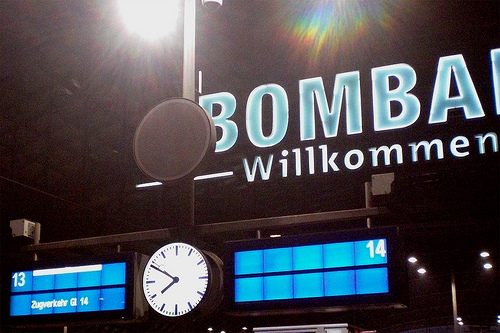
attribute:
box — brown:
[6, 217, 37, 242]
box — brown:
[368, 170, 399, 196]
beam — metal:
[19, 202, 389, 255]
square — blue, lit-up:
[232, 252, 259, 273]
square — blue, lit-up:
[262, 251, 289, 267]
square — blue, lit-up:
[297, 246, 323, 266]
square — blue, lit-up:
[326, 241, 361, 263]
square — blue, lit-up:
[361, 270, 391, 292]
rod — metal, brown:
[21, 204, 387, 257]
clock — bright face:
[126, 244, 211, 330]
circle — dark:
[130, 97, 217, 185]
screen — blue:
[17, 263, 130, 318]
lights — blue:
[232, 237, 392, 302]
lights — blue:
[10, 261, 129, 314]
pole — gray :
[180, 3, 198, 96]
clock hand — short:
[160, 280, 176, 293]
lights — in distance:
[400, 249, 498, 276]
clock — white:
[137, 236, 217, 321]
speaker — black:
[121, 87, 269, 212]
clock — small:
[106, 227, 241, 323]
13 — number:
[6, 268, 36, 291]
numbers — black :
[145, 244, 204, 314]